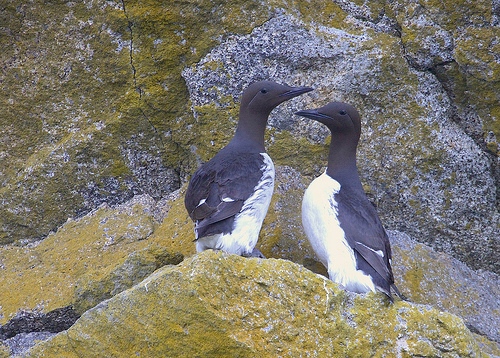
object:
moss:
[0, 341, 14, 358]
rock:
[10, 251, 500, 358]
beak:
[285, 87, 315, 98]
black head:
[239, 79, 314, 118]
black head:
[293, 99, 361, 136]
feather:
[192, 202, 241, 229]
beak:
[294, 107, 323, 121]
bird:
[288, 102, 393, 307]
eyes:
[262, 87, 269, 95]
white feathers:
[352, 241, 383, 256]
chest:
[301, 172, 353, 269]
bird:
[182, 81, 315, 257]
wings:
[338, 186, 391, 284]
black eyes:
[338, 108, 347, 115]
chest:
[235, 152, 274, 252]